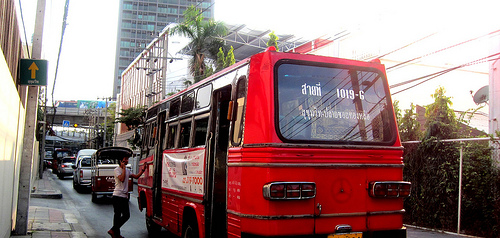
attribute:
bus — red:
[110, 60, 392, 216]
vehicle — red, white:
[85, 143, 134, 205]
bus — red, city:
[161, 66, 459, 237]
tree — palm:
[166, 2, 230, 74]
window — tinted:
[165, 94, 182, 120]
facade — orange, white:
[108, 23, 173, 132]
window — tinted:
[132, 51, 424, 236]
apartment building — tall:
[90, 5, 222, 80]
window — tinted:
[147, 127, 162, 147]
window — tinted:
[179, 89, 196, 114]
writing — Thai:
[293, 75, 374, 122]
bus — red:
[123, 44, 412, 232]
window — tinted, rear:
[272, 56, 397, 143]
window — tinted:
[192, 117, 204, 150]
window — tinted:
[179, 122, 191, 146]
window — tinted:
[164, 125, 175, 148]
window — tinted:
[167, 99, 179, 117]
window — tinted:
[192, 83, 209, 107]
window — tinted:
[273, 63, 399, 143]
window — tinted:
[149, 122, 157, 143]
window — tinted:
[141, 122, 147, 144]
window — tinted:
[226, 71, 250, 151]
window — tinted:
[192, 115, 208, 145]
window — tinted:
[140, 107, 162, 117]